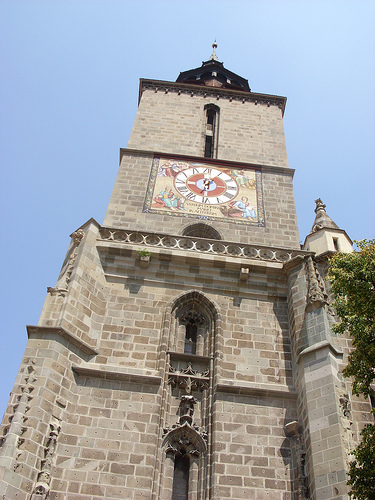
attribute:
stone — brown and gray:
[243, 355, 268, 368]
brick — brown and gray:
[125, 326, 140, 335]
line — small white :
[186, 179, 198, 187]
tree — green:
[323, 237, 374, 398]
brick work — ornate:
[0, 339, 70, 499]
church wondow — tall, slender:
[205, 111, 214, 158]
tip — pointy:
[207, 37, 220, 63]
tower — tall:
[302, 198, 354, 255]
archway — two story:
[150, 289, 226, 497]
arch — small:
[166, 220, 232, 239]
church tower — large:
[25, 36, 366, 456]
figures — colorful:
[148, 156, 257, 220]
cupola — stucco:
[300, 197, 353, 254]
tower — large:
[0, 38, 373, 497]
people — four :
[156, 155, 182, 174]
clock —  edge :
[151, 151, 273, 226]